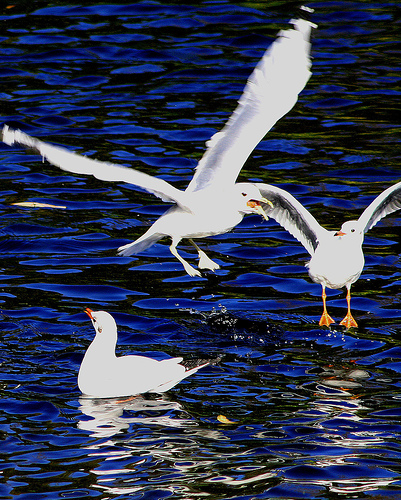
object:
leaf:
[217, 415, 237, 425]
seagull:
[60, 294, 222, 399]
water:
[0, 3, 401, 500]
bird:
[0, 20, 315, 279]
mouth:
[246, 195, 274, 221]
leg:
[168, 244, 201, 278]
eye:
[241, 191, 247, 198]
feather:
[268, 21, 311, 80]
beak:
[333, 230, 346, 237]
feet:
[318, 311, 335, 328]